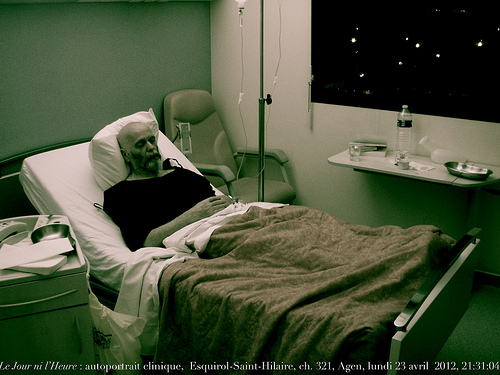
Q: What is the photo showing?
A: It is showing a hospital.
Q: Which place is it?
A: It is a hospital.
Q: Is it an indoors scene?
A: Yes, it is indoors.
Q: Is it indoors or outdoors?
A: It is indoors.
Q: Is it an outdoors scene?
A: No, it is indoors.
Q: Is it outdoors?
A: No, it is indoors.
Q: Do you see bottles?
A: Yes, there is a bottle.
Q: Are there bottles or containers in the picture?
A: Yes, there is a bottle.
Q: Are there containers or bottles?
A: Yes, there is a bottle.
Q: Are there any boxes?
A: No, there are no boxes.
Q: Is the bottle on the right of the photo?
A: Yes, the bottle is on the right of the image.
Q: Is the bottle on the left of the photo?
A: No, the bottle is on the right of the image.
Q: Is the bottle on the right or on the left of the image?
A: The bottle is on the right of the image.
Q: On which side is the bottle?
A: The bottle is on the right of the image.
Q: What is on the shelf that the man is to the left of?
A: The bottle is on the shelf.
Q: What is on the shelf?
A: The bottle is on the shelf.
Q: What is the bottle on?
A: The bottle is on the shelf.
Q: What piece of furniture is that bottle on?
A: The bottle is on the shelf.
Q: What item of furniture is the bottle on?
A: The bottle is on the shelf.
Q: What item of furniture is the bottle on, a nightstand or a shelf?
A: The bottle is on a shelf.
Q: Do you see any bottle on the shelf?
A: Yes, there is a bottle on the shelf.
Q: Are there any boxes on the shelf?
A: No, there is a bottle on the shelf.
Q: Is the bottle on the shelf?
A: Yes, the bottle is on the shelf.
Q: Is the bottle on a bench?
A: No, the bottle is on the shelf.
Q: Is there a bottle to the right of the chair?
A: Yes, there is a bottle to the right of the chair.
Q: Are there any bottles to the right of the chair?
A: Yes, there is a bottle to the right of the chair.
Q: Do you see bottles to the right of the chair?
A: Yes, there is a bottle to the right of the chair.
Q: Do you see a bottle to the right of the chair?
A: Yes, there is a bottle to the right of the chair.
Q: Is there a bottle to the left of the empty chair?
A: No, the bottle is to the right of the chair.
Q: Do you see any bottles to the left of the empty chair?
A: No, the bottle is to the right of the chair.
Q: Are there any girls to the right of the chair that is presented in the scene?
A: No, there is a bottle to the right of the chair.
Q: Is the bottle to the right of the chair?
A: Yes, the bottle is to the right of the chair.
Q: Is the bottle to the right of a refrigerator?
A: No, the bottle is to the right of the chair.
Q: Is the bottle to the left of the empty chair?
A: No, the bottle is to the right of the chair.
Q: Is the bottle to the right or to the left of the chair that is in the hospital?
A: The bottle is to the right of the chair.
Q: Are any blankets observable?
A: Yes, there is a blanket.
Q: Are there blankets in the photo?
A: Yes, there is a blanket.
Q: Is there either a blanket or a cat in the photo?
A: Yes, there is a blanket.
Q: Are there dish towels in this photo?
A: No, there are no dish towels.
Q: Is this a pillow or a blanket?
A: This is a blanket.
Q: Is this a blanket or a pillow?
A: This is a blanket.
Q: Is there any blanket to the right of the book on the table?
A: Yes, there is a blanket to the right of the book.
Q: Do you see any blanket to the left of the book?
A: No, the blanket is to the right of the book.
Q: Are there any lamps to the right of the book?
A: No, there is a blanket to the right of the book.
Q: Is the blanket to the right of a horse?
A: No, the blanket is to the right of a book.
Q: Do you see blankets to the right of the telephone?
A: Yes, there is a blanket to the right of the telephone.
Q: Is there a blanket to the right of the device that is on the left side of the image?
A: Yes, there is a blanket to the right of the telephone.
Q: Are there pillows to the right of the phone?
A: No, there is a blanket to the right of the phone.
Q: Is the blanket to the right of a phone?
A: Yes, the blanket is to the right of a phone.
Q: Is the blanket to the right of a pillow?
A: No, the blanket is to the right of a phone.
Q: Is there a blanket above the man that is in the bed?
A: Yes, there is a blanket above the man.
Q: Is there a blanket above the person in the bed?
A: Yes, there is a blanket above the man.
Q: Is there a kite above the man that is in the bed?
A: No, there is a blanket above the man.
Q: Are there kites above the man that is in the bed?
A: No, there is a blanket above the man.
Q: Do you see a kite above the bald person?
A: No, there is a blanket above the man.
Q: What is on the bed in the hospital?
A: The blanket is on the bed.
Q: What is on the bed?
A: The blanket is on the bed.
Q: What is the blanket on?
A: The blanket is on the bed.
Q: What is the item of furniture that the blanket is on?
A: The piece of furniture is a bed.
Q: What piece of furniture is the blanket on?
A: The blanket is on the bed.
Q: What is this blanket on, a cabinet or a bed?
A: The blanket is on a bed.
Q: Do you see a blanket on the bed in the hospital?
A: Yes, there is a blanket on the bed.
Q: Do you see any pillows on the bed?
A: No, there is a blanket on the bed.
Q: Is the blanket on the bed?
A: Yes, the blanket is on the bed.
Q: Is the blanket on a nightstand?
A: No, the blanket is on the bed.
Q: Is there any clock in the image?
A: No, there are no clocks.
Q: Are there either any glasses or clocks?
A: No, there are no clocks or glasses.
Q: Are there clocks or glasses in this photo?
A: No, there are no clocks or glasses.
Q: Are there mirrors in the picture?
A: No, there are no mirrors.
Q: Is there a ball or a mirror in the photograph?
A: No, there are no mirrors or balls.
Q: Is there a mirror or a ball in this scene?
A: No, there are no mirrors or balls.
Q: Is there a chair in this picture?
A: Yes, there is a chair.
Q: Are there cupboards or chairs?
A: Yes, there is a chair.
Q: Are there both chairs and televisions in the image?
A: No, there is a chair but no televisions.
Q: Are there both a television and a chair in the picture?
A: No, there is a chair but no televisions.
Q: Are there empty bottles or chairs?
A: Yes, there is an empty chair.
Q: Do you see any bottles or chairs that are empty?
A: Yes, the chair is empty.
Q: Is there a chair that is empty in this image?
A: Yes, there is an empty chair.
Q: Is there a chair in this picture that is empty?
A: Yes, there is a chair that is empty.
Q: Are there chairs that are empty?
A: Yes, there is a chair that is empty.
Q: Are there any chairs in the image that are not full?
A: Yes, there is a empty chair.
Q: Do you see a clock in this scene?
A: No, there are no clocks.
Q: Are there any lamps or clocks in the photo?
A: No, there are no clocks or lamps.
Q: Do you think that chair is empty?
A: Yes, the chair is empty.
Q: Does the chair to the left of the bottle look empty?
A: Yes, the chair is empty.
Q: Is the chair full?
A: No, the chair is empty.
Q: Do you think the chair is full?
A: No, the chair is empty.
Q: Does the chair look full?
A: No, the chair is empty.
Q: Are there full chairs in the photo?
A: No, there is a chair but it is empty.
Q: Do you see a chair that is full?
A: No, there is a chair but it is empty.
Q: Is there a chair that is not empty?
A: No, there is a chair but it is empty.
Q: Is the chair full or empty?
A: The chair is empty.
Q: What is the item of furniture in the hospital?
A: The piece of furniture is a chair.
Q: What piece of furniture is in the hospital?
A: The piece of furniture is a chair.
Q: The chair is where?
A: The chair is in the hospital.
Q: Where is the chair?
A: The chair is in the hospital.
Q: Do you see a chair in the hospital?
A: Yes, there is a chair in the hospital.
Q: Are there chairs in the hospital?
A: Yes, there is a chair in the hospital.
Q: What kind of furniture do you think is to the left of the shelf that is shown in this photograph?
A: The piece of furniture is a chair.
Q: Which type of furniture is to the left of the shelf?
A: The piece of furniture is a chair.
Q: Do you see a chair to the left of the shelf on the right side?
A: Yes, there is a chair to the left of the shelf.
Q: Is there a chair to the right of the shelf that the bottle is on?
A: No, the chair is to the left of the shelf.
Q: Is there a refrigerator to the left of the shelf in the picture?
A: No, there is a chair to the left of the shelf.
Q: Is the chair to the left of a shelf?
A: Yes, the chair is to the left of a shelf.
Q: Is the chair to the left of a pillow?
A: No, the chair is to the left of a shelf.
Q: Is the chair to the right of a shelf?
A: No, the chair is to the left of a shelf.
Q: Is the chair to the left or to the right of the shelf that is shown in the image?
A: The chair is to the left of the shelf.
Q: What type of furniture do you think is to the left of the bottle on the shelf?
A: The piece of furniture is a chair.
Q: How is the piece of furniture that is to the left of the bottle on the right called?
A: The piece of furniture is a chair.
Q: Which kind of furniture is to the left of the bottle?
A: The piece of furniture is a chair.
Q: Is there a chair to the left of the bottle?
A: Yes, there is a chair to the left of the bottle.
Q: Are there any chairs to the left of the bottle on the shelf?
A: Yes, there is a chair to the left of the bottle.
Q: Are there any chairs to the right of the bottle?
A: No, the chair is to the left of the bottle.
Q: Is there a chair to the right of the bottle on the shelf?
A: No, the chair is to the left of the bottle.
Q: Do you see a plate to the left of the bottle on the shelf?
A: No, there is a chair to the left of the bottle.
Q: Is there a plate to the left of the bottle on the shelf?
A: No, there is a chair to the left of the bottle.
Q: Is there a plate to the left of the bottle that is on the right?
A: No, there is a chair to the left of the bottle.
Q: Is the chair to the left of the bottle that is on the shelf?
A: Yes, the chair is to the left of the bottle.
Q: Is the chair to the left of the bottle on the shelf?
A: Yes, the chair is to the left of the bottle.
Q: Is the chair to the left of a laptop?
A: No, the chair is to the left of the bottle.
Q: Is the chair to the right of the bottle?
A: No, the chair is to the left of the bottle.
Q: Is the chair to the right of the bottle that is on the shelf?
A: No, the chair is to the left of the bottle.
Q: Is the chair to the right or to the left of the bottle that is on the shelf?
A: The chair is to the left of the bottle.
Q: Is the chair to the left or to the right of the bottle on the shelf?
A: The chair is to the left of the bottle.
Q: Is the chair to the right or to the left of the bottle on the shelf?
A: The chair is to the left of the bottle.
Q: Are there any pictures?
A: No, there are no pictures.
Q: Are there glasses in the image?
A: No, there are no glasses.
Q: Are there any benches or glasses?
A: No, there are no glasses or benches.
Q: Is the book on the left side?
A: Yes, the book is on the left of the image.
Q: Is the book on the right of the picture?
A: No, the book is on the left of the image.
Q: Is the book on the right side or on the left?
A: The book is on the left of the image.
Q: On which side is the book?
A: The book is on the left of the image.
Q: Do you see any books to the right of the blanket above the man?
A: No, the book is to the left of the blanket.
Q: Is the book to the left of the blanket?
A: Yes, the book is to the left of the blanket.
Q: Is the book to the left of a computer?
A: No, the book is to the left of the blanket.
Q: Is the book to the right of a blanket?
A: No, the book is to the left of a blanket.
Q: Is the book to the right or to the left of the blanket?
A: The book is to the left of the blanket.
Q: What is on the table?
A: The book is on the table.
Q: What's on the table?
A: The book is on the table.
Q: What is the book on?
A: The book is on the table.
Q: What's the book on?
A: The book is on the table.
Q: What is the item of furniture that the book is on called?
A: The piece of furniture is a table.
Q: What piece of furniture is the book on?
A: The book is on the table.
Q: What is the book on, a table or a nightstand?
A: The book is on a table.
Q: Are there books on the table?
A: Yes, there is a book on the table.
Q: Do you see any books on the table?
A: Yes, there is a book on the table.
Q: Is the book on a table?
A: Yes, the book is on a table.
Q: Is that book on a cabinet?
A: No, the book is on a table.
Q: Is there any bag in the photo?
A: Yes, there is a bag.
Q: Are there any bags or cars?
A: Yes, there is a bag.